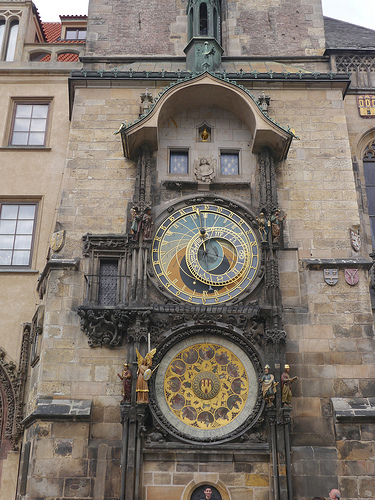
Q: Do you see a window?
A: Yes, there is a window.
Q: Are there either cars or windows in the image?
A: Yes, there is a window.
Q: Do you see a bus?
A: No, there are no buses.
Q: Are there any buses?
A: No, there are no buses.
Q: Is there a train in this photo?
A: No, there are no trains.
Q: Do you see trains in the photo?
A: No, there are no trains.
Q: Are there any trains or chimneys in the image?
A: No, there are no trains or chimneys.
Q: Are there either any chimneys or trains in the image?
A: No, there are no trains or chimneys.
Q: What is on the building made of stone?
A: The statue is on the building.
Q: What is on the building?
A: The statue is on the building.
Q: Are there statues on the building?
A: Yes, there is a statue on the building.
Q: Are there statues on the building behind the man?
A: Yes, there is a statue on the building.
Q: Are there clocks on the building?
A: No, there is a statue on the building.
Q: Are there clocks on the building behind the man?
A: No, there is a statue on the building.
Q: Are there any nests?
A: No, there are no nests.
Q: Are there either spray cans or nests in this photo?
A: No, there are no nests or spray cans.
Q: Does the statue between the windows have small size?
A: Yes, the statue is small.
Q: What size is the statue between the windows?
A: The statue is small.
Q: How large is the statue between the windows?
A: The statue is small.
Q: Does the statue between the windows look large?
A: No, the statue is small.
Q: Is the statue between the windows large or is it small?
A: The statue is small.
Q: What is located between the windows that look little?
A: The statue is between the windows.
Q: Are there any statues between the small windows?
A: Yes, there is a statue between the windows.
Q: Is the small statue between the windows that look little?
A: Yes, the statue is between the windows.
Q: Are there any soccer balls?
A: No, there are no soccer balls.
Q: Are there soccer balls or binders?
A: No, there are no soccer balls or binders.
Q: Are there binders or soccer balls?
A: No, there are no soccer balls or binders.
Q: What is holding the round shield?
A: The statue is holding the shield.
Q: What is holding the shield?
A: The statue is holding the shield.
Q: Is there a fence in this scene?
A: No, there are no fences.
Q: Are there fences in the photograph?
A: No, there are no fences.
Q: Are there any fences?
A: No, there are no fences.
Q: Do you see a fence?
A: No, there are no fences.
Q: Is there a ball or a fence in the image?
A: No, there are no fences or balls.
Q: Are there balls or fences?
A: No, there are no fences or balls.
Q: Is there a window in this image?
A: Yes, there are windows.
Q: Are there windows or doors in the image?
A: Yes, there are windows.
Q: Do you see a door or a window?
A: Yes, there are windows.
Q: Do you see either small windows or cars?
A: Yes, there are small windows.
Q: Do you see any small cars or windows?
A: Yes, there are small windows.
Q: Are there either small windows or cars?
A: Yes, there are small windows.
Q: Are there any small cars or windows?
A: Yes, there are small windows.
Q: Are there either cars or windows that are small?
A: Yes, the windows are small.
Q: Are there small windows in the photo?
A: Yes, there are small windows.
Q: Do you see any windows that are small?
A: Yes, there are windows that are small.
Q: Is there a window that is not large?
A: Yes, there are small windows.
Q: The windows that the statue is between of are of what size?
A: The windows are small.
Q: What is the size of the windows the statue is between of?
A: The windows are small.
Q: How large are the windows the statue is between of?
A: The windows are small.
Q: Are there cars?
A: No, there are no cars.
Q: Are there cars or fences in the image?
A: No, there are no cars or fences.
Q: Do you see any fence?
A: No, there are no fences.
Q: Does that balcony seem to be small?
A: Yes, the balcony is small.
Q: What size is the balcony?
A: The balcony is small.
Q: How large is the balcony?
A: The balcony is small.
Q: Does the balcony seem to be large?
A: No, the balcony is small.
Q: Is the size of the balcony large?
A: No, the balcony is small.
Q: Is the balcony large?
A: No, the balcony is small.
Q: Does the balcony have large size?
A: No, the balcony is small.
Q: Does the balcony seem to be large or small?
A: The balcony is small.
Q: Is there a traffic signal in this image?
A: No, there are no traffic lights.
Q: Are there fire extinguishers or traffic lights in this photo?
A: No, there are no traffic lights or fire extinguishers.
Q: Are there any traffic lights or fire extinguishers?
A: No, there are no traffic lights or fire extinguishers.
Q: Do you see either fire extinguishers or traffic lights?
A: No, there are no traffic lights or fire extinguishers.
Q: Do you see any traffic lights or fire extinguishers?
A: No, there are no traffic lights or fire extinguishers.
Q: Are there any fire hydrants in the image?
A: No, there are no fire hydrants.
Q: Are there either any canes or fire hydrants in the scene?
A: No, there are no fire hydrants or canes.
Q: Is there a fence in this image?
A: No, there are no fences.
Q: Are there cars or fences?
A: No, there are no fences or cars.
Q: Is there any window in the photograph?
A: Yes, there is a window.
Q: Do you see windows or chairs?
A: Yes, there is a window.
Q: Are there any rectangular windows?
A: Yes, there is a rectangular window.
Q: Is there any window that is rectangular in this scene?
A: Yes, there is a rectangular window.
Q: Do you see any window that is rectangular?
A: Yes, there is a window that is rectangular.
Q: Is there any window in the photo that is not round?
A: Yes, there is a rectangular window.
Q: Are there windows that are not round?
A: Yes, there is a rectangular window.